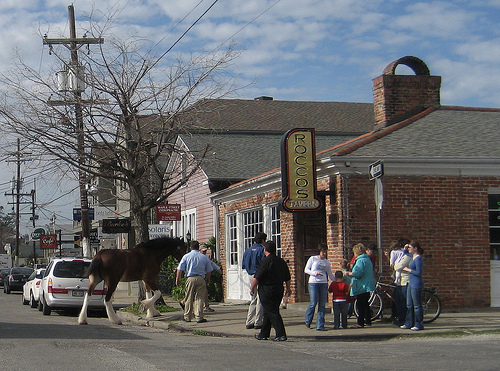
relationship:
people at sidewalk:
[175, 238, 445, 343] [208, 298, 249, 336]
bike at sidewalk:
[361, 278, 449, 322] [208, 298, 249, 336]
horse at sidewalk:
[81, 233, 187, 329] [208, 298, 249, 336]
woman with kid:
[299, 247, 332, 330] [322, 265, 355, 333]